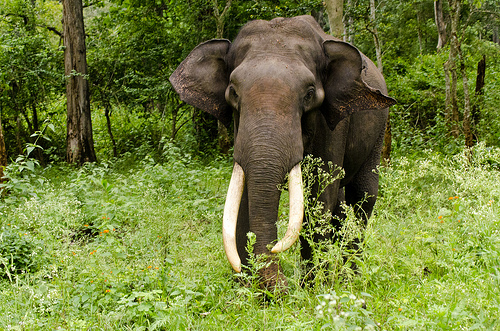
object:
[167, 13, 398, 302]
elephant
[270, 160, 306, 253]
tusk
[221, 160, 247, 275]
tusk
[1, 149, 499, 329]
brush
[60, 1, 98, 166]
trunk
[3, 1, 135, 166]
tree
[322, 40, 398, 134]
ear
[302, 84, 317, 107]
eye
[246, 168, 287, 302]
trunk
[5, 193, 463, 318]
flowers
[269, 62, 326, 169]
side of head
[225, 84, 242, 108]
eye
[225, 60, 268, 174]
side of head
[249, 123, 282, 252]
wrinkles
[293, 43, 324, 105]
temples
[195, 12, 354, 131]
head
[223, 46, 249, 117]
temple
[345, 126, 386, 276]
back leg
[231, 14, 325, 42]
bumpy top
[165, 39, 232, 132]
ear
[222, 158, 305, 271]
tusks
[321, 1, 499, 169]
trees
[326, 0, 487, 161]
trunks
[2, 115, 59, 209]
leaves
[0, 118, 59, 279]
plant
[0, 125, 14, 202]
stump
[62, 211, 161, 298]
plant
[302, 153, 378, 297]
plant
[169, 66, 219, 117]
spots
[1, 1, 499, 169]
leaves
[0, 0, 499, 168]
area